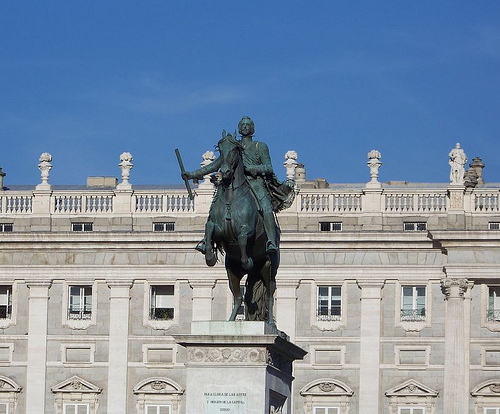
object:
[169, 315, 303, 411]
pedestal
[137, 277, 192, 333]
window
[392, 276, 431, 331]
window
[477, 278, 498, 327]
window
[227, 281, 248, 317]
window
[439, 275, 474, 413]
stone column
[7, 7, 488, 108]
sky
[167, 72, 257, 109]
cloud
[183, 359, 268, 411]
writing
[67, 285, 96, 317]
window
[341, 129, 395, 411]
column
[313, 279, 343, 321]
window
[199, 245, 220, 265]
feet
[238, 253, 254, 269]
feet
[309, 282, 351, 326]
window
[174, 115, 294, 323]
statue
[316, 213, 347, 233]
window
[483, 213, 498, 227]
window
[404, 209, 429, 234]
window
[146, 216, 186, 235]
window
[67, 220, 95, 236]
window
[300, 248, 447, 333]
windows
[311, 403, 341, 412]
window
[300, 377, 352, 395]
stone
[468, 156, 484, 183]
chimney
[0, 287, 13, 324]
window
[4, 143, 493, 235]
roof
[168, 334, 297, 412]
column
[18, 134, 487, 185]
posts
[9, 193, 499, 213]
barriers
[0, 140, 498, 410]
building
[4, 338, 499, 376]
design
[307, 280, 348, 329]
frame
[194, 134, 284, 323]
horse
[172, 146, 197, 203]
sword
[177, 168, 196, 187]
hand